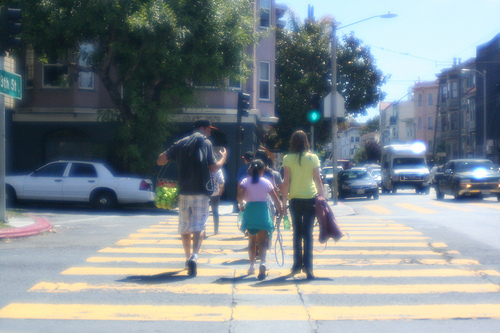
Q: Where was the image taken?
A: It was taken at the street.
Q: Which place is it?
A: It is a street.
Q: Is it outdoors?
A: Yes, it is outdoors.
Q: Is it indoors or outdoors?
A: It is outdoors.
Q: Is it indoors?
A: No, it is outdoors.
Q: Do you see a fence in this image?
A: No, there are no fences.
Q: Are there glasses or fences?
A: No, there are no fences or glasses.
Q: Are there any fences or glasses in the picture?
A: No, there are no fences or glasses.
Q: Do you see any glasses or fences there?
A: No, there are no fences or glasses.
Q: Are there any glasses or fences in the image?
A: No, there are no fences or glasses.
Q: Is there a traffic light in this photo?
A: Yes, there is a traffic light.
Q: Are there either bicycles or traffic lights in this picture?
A: Yes, there is a traffic light.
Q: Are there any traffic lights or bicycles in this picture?
A: Yes, there is a traffic light.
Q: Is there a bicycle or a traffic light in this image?
A: Yes, there is a traffic light.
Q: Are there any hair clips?
A: No, there are no hair clips.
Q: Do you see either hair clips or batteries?
A: No, there are no hair clips or batteries.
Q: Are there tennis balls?
A: Yes, there are tennis balls.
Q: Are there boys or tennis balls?
A: Yes, there are tennis balls.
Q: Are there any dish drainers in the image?
A: No, there are no dish drainers.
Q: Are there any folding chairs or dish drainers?
A: No, there are no dish drainers or folding chairs.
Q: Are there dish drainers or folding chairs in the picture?
A: No, there are no dish drainers or folding chairs.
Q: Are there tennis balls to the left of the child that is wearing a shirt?
A: Yes, there are tennis balls to the left of the child.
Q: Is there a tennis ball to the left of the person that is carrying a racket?
A: Yes, there are tennis balls to the left of the child.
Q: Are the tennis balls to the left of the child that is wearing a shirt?
A: Yes, the tennis balls are to the left of the child.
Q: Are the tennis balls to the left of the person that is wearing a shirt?
A: Yes, the tennis balls are to the left of the child.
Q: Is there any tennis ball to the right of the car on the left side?
A: Yes, there are tennis balls to the right of the car.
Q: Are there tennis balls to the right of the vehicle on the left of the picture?
A: Yes, there are tennis balls to the right of the car.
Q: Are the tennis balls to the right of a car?
A: Yes, the tennis balls are to the right of a car.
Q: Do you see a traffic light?
A: Yes, there is a traffic light.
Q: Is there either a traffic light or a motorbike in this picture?
A: Yes, there is a traffic light.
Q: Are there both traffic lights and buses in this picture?
A: No, there is a traffic light but no buses.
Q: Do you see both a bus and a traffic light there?
A: No, there is a traffic light but no buses.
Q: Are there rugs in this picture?
A: No, there are no rugs.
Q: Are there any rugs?
A: No, there are no rugs.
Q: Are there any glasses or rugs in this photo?
A: No, there are no rugs or glasses.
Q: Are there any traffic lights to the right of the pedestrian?
A: Yes, there is a traffic light to the right of the pedestrian.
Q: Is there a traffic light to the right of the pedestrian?
A: Yes, there is a traffic light to the right of the pedestrian.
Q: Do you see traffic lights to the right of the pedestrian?
A: Yes, there is a traffic light to the right of the pedestrian.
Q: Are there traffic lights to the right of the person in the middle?
A: Yes, there is a traffic light to the right of the pedestrian.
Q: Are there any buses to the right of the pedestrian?
A: No, there is a traffic light to the right of the pedestrian.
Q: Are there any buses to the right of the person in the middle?
A: No, there is a traffic light to the right of the pedestrian.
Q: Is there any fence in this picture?
A: No, there are no fences.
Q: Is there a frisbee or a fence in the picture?
A: No, there are no fences or frisbees.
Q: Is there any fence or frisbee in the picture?
A: No, there are no fences or frisbees.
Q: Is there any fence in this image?
A: No, there are no fences.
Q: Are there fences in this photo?
A: No, there are no fences.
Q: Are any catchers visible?
A: No, there are no catchers.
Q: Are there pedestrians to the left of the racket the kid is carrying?
A: Yes, there is a pedestrian to the left of the racket.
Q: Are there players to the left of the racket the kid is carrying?
A: No, there is a pedestrian to the left of the racket.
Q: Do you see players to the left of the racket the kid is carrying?
A: No, there is a pedestrian to the left of the racket.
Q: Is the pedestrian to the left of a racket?
A: Yes, the pedestrian is to the left of a racket.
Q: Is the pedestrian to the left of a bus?
A: No, the pedestrian is to the left of a racket.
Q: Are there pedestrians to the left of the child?
A: Yes, there is a pedestrian to the left of the child.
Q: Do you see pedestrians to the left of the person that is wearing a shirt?
A: Yes, there is a pedestrian to the left of the child.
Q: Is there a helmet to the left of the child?
A: No, there is a pedestrian to the left of the child.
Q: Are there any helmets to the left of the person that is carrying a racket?
A: No, there is a pedestrian to the left of the child.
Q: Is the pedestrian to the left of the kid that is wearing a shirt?
A: Yes, the pedestrian is to the left of the kid.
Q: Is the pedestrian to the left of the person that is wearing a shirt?
A: Yes, the pedestrian is to the left of the kid.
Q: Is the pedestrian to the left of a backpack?
A: No, the pedestrian is to the left of the kid.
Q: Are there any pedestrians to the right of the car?
A: Yes, there is a pedestrian to the right of the car.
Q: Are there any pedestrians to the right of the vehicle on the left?
A: Yes, there is a pedestrian to the right of the car.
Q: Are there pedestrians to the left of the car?
A: No, the pedestrian is to the right of the car.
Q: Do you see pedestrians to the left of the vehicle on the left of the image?
A: No, the pedestrian is to the right of the car.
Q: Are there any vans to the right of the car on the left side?
A: No, there is a pedestrian to the right of the car.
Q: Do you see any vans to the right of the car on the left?
A: No, there is a pedestrian to the right of the car.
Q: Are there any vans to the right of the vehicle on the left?
A: No, there is a pedestrian to the right of the car.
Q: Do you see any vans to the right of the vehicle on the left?
A: No, there is a pedestrian to the right of the car.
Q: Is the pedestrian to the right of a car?
A: Yes, the pedestrian is to the right of a car.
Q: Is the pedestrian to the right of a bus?
A: No, the pedestrian is to the right of a car.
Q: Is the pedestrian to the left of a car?
A: No, the pedestrian is to the right of a car.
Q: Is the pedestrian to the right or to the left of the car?
A: The pedestrian is to the right of the car.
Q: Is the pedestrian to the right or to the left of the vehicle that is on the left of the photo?
A: The pedestrian is to the right of the car.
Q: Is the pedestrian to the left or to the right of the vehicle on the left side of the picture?
A: The pedestrian is to the right of the car.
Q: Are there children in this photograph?
A: Yes, there is a child.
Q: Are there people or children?
A: Yes, there is a child.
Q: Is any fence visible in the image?
A: No, there are no fences.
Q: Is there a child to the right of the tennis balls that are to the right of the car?
A: Yes, there is a child to the right of the tennis balls.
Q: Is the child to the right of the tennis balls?
A: Yes, the child is to the right of the tennis balls.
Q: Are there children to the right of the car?
A: Yes, there is a child to the right of the car.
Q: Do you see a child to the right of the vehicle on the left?
A: Yes, there is a child to the right of the car.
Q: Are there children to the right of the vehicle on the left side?
A: Yes, there is a child to the right of the car.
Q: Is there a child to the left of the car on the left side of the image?
A: No, the child is to the right of the car.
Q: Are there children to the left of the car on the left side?
A: No, the child is to the right of the car.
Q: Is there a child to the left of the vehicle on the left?
A: No, the child is to the right of the car.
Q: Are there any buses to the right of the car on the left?
A: No, there is a child to the right of the car.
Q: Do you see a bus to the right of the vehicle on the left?
A: No, there is a child to the right of the car.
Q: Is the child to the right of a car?
A: Yes, the child is to the right of a car.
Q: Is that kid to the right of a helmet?
A: No, the kid is to the right of a car.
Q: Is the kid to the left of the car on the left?
A: No, the kid is to the right of the car.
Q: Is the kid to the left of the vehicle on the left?
A: No, the kid is to the right of the car.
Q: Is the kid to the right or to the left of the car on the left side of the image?
A: The kid is to the right of the car.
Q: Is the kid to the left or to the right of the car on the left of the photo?
A: The kid is to the right of the car.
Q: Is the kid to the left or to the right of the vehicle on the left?
A: The kid is to the right of the car.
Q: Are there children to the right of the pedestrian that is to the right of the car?
A: Yes, there is a child to the right of the pedestrian.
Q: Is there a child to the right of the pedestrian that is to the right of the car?
A: Yes, there is a child to the right of the pedestrian.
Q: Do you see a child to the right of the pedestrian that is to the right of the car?
A: Yes, there is a child to the right of the pedestrian.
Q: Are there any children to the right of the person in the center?
A: Yes, there is a child to the right of the pedestrian.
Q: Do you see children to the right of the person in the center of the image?
A: Yes, there is a child to the right of the pedestrian.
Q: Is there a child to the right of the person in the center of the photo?
A: Yes, there is a child to the right of the pedestrian.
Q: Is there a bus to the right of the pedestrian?
A: No, there is a child to the right of the pedestrian.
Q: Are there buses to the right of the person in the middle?
A: No, there is a child to the right of the pedestrian.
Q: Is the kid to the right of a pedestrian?
A: Yes, the kid is to the right of a pedestrian.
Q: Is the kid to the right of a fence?
A: No, the kid is to the right of a pedestrian.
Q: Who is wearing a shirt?
A: The kid is wearing a shirt.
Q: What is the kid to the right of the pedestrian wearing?
A: The child is wearing a shirt.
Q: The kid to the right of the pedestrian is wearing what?
A: The child is wearing a shirt.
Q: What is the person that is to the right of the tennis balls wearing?
A: The child is wearing a shirt.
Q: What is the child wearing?
A: The child is wearing a shirt.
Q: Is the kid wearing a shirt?
A: Yes, the kid is wearing a shirt.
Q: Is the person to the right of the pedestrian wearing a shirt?
A: Yes, the kid is wearing a shirt.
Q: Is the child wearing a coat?
A: No, the child is wearing a shirt.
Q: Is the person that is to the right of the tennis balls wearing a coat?
A: No, the child is wearing a shirt.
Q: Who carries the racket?
A: The child carries the racket.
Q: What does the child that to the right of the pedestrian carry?
A: The child carries a tennis racket.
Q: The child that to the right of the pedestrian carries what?
A: The child carries a tennis racket.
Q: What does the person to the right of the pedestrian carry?
A: The child carries a tennis racket.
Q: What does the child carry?
A: The child carries a tennis racket.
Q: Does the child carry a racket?
A: Yes, the child carries a racket.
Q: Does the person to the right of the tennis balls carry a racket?
A: Yes, the child carries a racket.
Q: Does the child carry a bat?
A: No, the child carries a racket.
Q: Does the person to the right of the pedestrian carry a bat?
A: No, the child carries a racket.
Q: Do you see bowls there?
A: No, there are no bowls.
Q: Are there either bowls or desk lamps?
A: No, there are no bowls or desk lamps.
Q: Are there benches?
A: No, there are no benches.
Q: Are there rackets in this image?
A: Yes, there is a racket.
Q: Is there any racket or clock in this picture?
A: Yes, there is a racket.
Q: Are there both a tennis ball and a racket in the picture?
A: Yes, there are both a racket and a tennis ball.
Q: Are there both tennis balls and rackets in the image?
A: Yes, there are both a racket and a tennis ball.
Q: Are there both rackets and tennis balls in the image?
A: Yes, there are both a racket and a tennis ball.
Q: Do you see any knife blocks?
A: No, there are no knife blocks.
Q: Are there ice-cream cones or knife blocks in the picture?
A: No, there are no knife blocks or ice-cream cones.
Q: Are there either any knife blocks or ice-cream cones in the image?
A: No, there are no knife blocks or ice-cream cones.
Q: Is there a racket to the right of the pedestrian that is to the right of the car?
A: Yes, there is a racket to the right of the pedestrian.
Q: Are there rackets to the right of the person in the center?
A: Yes, there is a racket to the right of the pedestrian.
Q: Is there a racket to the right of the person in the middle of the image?
A: Yes, there is a racket to the right of the pedestrian.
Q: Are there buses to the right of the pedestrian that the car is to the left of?
A: No, there is a racket to the right of the pedestrian.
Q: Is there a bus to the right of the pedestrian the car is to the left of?
A: No, there is a racket to the right of the pedestrian.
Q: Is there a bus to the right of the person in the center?
A: No, there is a racket to the right of the pedestrian.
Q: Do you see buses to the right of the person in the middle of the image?
A: No, there is a racket to the right of the pedestrian.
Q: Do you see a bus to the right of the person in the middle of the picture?
A: No, there is a racket to the right of the pedestrian.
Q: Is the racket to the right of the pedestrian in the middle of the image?
A: Yes, the racket is to the right of the pedestrian.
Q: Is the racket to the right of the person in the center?
A: Yes, the racket is to the right of the pedestrian.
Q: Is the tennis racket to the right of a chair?
A: No, the tennis racket is to the right of the pedestrian.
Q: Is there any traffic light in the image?
A: Yes, there is a traffic light.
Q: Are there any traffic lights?
A: Yes, there is a traffic light.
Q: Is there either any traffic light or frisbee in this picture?
A: Yes, there is a traffic light.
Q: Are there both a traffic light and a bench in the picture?
A: No, there is a traffic light but no benches.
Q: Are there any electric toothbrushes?
A: No, there are no electric toothbrushes.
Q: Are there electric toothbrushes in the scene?
A: No, there are no electric toothbrushes.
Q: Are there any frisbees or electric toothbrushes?
A: No, there are no electric toothbrushes or frisbees.